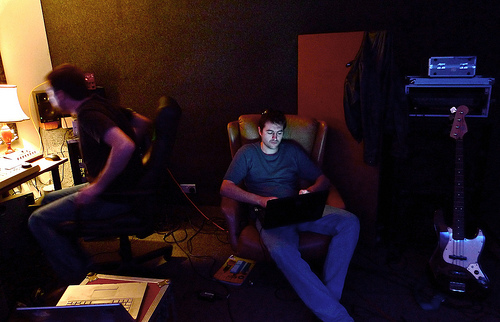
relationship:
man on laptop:
[210, 102, 366, 320] [241, 181, 333, 228]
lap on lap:
[255, 189, 329, 231] [255, 212, 354, 243]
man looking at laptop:
[218, 115, 361, 322] [254, 185, 331, 227]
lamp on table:
[2, 85, 24, 155] [1, 142, 67, 202]